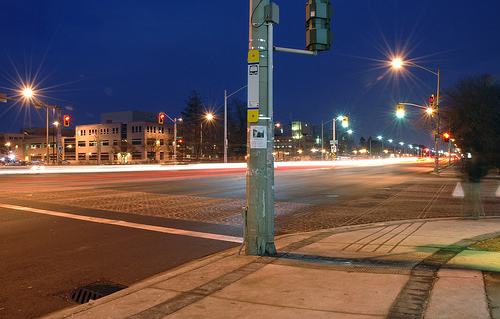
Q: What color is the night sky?
A: Blue.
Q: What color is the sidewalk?
A: Light grey.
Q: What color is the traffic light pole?
A: Dark grey.